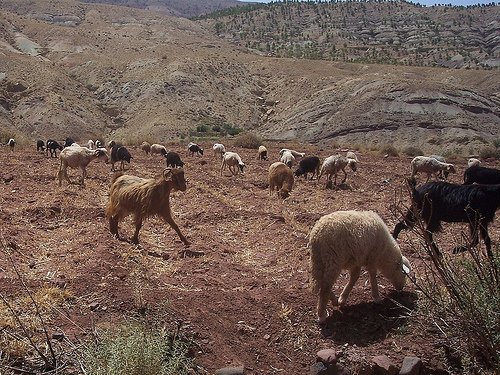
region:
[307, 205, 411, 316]
White goat grazing on a hill.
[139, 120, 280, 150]
Mountain valley where goats graze.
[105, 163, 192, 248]
Brown goat skipping across dirt.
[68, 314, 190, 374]
Weeds growing on the mountain.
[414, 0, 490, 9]
Blue skies show on the right.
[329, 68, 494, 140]
Hill with no plant life.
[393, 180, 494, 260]
Black goat black butt.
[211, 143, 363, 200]
Several goats grazing on a hill.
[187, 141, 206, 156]
Black goat with its head down.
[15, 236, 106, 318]
Pieces of mountain goat poop.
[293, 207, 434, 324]
female domesticated sheep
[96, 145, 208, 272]
male, domesticated goat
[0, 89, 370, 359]
hillside prarie during the daytime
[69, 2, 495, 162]
mountain range during daylight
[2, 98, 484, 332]
herd of domesticated sheep and goats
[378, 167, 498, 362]
barren bush in a prarie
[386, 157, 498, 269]
black goat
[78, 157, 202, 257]
brown goat with horns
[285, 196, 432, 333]
unshave, white sheep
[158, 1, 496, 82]
hillside sparsely covered with small trees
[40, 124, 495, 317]
Field of goats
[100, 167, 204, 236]
This goat is brown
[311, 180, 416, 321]
White sheep in foreground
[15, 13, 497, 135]
Hills in background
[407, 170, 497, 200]
Back of animal has ridge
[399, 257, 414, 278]
Sheep's right ear is white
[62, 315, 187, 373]
Small shrub on ground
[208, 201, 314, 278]
Mass of hay on floor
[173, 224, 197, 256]
Goat's front left foot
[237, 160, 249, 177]
Sheep's head is black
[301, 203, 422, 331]
a sheep eating dirt.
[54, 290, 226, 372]
a bush in a field.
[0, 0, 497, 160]
a large brown hillside.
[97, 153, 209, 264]
a sheep with horns.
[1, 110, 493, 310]
a herd of animals in a field.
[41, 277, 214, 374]
a wild bush growing in a dirt field.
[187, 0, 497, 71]
a tree covered hillside.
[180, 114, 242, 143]
a patch of green on a hill.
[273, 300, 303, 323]
dry grass in a field.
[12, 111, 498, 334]
a herd of sheep grazing on a dirt field.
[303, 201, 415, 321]
a white grazing sheep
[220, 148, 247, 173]
a white grazing sheep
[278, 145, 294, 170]
a white grazing sheep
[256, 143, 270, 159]
a white grazing sheep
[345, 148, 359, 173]
a white grazing sheep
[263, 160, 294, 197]
a brown grazing goat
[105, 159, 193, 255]
a walking brown goat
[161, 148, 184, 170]
a black walking goat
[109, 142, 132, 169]
a black walking goat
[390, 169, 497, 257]
a black walking goat